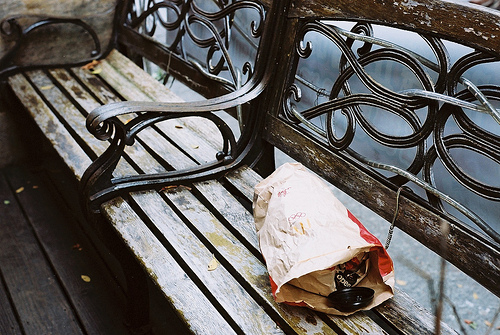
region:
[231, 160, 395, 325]
open bag laying on bench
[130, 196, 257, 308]
wood that makes seat of bench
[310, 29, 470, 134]
metal that makes back of bench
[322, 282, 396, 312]
black lid in trash bag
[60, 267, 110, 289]
leaf on ground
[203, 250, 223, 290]
yellow leaf on bench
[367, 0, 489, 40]
chipped paint on bench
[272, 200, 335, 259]
mcdonalds bag on bench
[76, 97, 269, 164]
arm rest on bench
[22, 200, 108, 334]
wooden boards in front of bench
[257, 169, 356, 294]
bag of trash on bench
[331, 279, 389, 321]
coffee lid in bag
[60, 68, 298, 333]
two park benches next to each other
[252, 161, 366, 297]
paper bag from fast food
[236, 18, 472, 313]
iron and wood park bench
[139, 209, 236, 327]
wooden slats on bench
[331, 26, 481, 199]
bench ironworking with cable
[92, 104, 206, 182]
iron park bench handle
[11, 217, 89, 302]
leaves on wooden floor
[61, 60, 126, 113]
leaf on park bench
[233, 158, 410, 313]
a bag of garbage.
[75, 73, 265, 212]
an arm rest on a bench.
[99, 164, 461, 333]
a seat on a bench.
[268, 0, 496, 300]
a back rest on a bench.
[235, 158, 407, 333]
a paper bag.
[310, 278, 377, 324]
a cup lid.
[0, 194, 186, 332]
a wooden ground.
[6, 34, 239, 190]
a wooden seat on a bench.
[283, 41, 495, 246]
a water way on a bench.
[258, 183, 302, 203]
print on a bag.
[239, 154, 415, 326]
Red and tan paper bag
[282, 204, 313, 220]
Olympic rings logo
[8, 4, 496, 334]
Metal and wood park bench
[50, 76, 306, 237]
Metal bench arm rest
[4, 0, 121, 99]
Tan and gray stone wall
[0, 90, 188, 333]
Dark brown wooden boardwalk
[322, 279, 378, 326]
Black plastic coffee cup lid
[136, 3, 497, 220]
Plastic tube style small lights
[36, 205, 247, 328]
Small gold fallen leaves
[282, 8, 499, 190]
Ornate curvy metal bench back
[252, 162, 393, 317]
a brown paper bag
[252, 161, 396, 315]
a brown bag on a bench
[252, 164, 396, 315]
paper bag with red trim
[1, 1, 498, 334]
a big wood and iron bench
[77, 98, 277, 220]
arm rail on a bench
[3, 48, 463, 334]
wooden slats of a bench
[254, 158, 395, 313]
litter on a park bench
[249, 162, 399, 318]
garbage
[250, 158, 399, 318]
paper sack on a bench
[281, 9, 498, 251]
iron lattice work